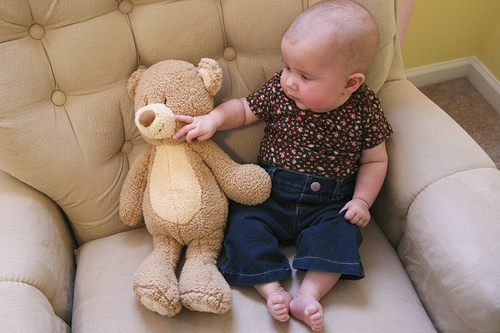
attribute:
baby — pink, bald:
[172, 1, 396, 332]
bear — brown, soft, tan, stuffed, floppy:
[120, 57, 271, 314]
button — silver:
[311, 180, 321, 193]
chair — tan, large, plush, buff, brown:
[0, 0, 498, 330]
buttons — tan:
[30, 2, 241, 159]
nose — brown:
[139, 109, 155, 126]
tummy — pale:
[142, 143, 225, 240]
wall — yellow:
[395, 3, 499, 81]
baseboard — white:
[404, 56, 499, 112]